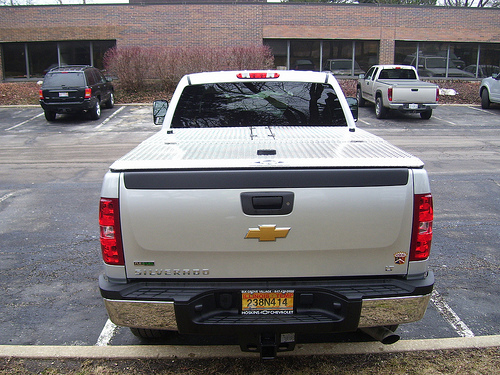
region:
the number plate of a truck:
[241, 291, 292, 311]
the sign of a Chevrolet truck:
[240, 215, 290, 245]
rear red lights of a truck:
[415, 193, 435, 260]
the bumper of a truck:
[96, 284, 440, 328]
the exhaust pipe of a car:
[368, 328, 410, 350]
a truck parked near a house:
[369, 57, 442, 119]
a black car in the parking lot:
[32, 63, 114, 128]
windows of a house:
[424, 43, 477, 79]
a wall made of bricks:
[131, 7, 248, 41]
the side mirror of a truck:
[149, 100, 170, 122]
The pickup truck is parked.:
[351, 42, 446, 142]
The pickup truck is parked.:
[94, 60, 439, 352]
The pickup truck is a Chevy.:
[91, 62, 443, 366]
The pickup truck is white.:
[93, 61, 440, 357]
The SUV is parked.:
[33, 57, 121, 132]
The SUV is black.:
[32, 57, 122, 142]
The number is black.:
[244, 294, 254, 311]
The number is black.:
[249, 294, 260, 311]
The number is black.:
[257, 293, 265, 308]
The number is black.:
[280, 293, 290, 309]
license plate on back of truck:
[231, 281, 303, 324]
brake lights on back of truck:
[86, 189, 442, 282]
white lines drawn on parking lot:
[91, 100, 130, 142]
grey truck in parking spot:
[93, 50, 443, 367]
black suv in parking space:
[25, 53, 127, 130]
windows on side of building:
[263, 33, 499, 83]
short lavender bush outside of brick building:
[96, 37, 279, 109]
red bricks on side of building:
[131, 10, 215, 35]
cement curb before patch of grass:
[0, 328, 498, 363]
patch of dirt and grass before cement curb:
[75, 360, 115, 372]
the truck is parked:
[127, 76, 424, 358]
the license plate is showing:
[226, 274, 401, 339]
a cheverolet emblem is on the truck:
[225, 217, 347, 238]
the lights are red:
[85, 193, 160, 289]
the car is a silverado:
[120, 251, 313, 288]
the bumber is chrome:
[95, 267, 392, 372]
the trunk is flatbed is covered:
[138, 122, 478, 168]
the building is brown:
[95, 11, 369, 95]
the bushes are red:
[118, 37, 309, 97]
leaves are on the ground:
[6, 83, 23, 96]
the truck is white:
[75, 36, 467, 353]